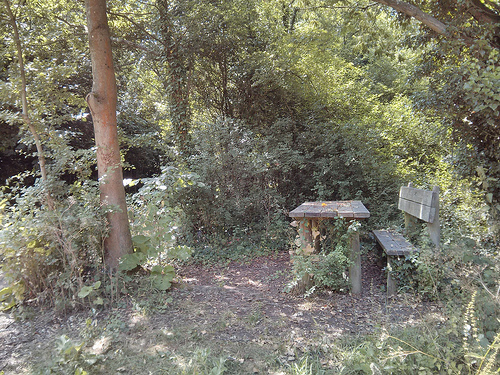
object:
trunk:
[82, 1, 141, 272]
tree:
[81, 0, 136, 272]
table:
[287, 198, 372, 296]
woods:
[208, 165, 233, 177]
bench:
[370, 179, 441, 297]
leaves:
[311, 66, 317, 68]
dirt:
[214, 275, 281, 317]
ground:
[0, 207, 500, 375]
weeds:
[116, 190, 193, 292]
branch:
[375, 0, 499, 70]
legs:
[348, 218, 362, 295]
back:
[397, 184, 440, 224]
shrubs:
[225, 127, 237, 229]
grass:
[0, 304, 500, 374]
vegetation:
[341, 39, 460, 145]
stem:
[90, 22, 110, 33]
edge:
[286, 206, 298, 219]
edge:
[427, 194, 443, 222]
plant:
[281, 215, 361, 295]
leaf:
[321, 202, 327, 207]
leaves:
[385, 235, 389, 238]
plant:
[154, 0, 304, 161]